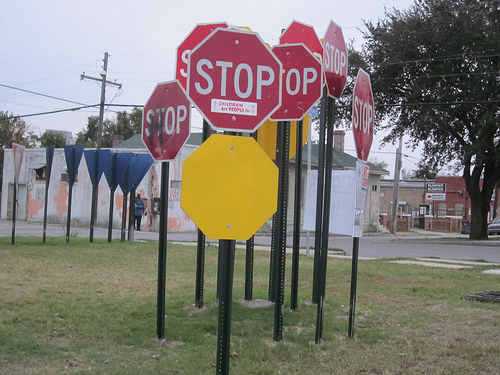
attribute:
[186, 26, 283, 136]
stop sign — red, grouped, clustered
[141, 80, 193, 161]
stop sign — red, clustered, grouped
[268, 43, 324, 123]
stop sign — clustered, grouped, red, white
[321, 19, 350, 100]
stop sign — red, clustered, grouped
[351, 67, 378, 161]
stop sign — red, grouped, clustered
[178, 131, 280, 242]
sign — octagonal, yellow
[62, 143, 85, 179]
sign — blue, triangular, clustered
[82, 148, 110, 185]
sign — clustered, blue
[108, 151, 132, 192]
sign — clustered, blue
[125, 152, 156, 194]
sign — clustered, blue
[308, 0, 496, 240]
tree — green, dark green, large, big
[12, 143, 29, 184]
sign — white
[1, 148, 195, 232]
building — white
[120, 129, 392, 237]
building — white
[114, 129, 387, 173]
roof — grey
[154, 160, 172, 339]
post — green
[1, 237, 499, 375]
grass — sparse, brown, green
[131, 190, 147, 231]
person — standing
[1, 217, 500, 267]
street — public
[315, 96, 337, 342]
pole — black